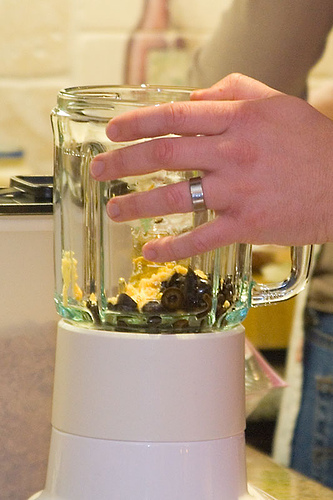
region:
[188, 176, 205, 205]
a silver ring on a finger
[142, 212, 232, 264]
a finger on a hand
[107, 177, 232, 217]
a finger on a hand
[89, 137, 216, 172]
a finger on a hand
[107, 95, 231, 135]
a finger on a hand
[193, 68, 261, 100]
a thumb on a hand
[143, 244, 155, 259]
a fingernail on a finger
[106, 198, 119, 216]
a fingernail on a finger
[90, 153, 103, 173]
a fingernail on a finger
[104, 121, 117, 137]
a fingernail on a finger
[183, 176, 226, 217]
The woman is wearing a ring.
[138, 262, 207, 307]
Black olives in the blender.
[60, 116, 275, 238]
A hand on the blender.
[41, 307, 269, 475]
The bottom of the blender is white.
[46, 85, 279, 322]
The top of the blender is glass.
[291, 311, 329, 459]
The person is wearing jeans.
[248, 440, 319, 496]
The blender is sitting on the counter top.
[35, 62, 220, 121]
The blender is open on the top.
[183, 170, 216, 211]
The ring is silver.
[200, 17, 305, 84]
The person is wearing a long sleeve shirt.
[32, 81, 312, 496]
an electric blender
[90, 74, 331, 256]
a person's left hand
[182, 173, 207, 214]
a silver wedding band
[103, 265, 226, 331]
a pile of cut olives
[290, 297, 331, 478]
a pair of blue jeans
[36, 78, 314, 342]
a clear glass blender bowl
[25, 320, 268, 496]
white plastic blender bottom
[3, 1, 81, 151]
cream tiled wall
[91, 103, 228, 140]
a person's index finger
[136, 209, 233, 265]
a person's pinky finger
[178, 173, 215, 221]
silver wedding band on a ring finger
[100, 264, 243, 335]
sliced up black olives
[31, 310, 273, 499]
plastic white blender base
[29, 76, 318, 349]
transparent glass blender vessel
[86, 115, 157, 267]
short trimmed finger nails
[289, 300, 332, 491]
blurry pair of blue jeans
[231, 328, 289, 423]
transparent plastic ziplock bag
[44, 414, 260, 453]
seam in the plastic of the blender base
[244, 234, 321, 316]
transparent glass handle of blender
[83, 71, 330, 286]
pinkish peach coloured hand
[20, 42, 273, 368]
the blender is clear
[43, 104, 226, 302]
the blender is clear